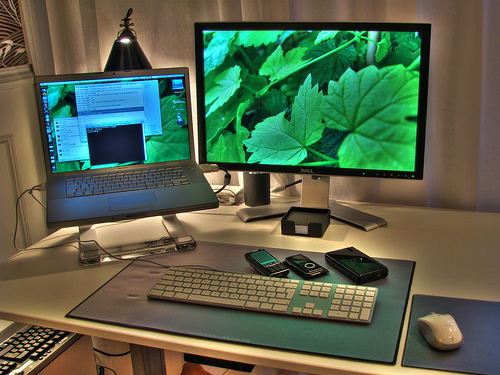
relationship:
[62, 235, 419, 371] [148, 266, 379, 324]
mat underneath keyboard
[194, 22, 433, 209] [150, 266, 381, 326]
monitor behind keyboard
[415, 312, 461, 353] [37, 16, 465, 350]
mouse to computer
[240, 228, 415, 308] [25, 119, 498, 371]
phones on desk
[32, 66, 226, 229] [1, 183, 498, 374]
computer on desk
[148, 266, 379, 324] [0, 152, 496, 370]
keyboard on desk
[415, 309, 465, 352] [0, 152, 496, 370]
mouse on desk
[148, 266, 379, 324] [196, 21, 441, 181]
keyboard in front of monitor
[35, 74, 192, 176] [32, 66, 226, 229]
screen of computer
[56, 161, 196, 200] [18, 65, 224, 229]
keyboard on laptop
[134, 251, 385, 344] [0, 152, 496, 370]
keyboard on desk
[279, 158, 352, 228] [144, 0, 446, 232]
stand of computer